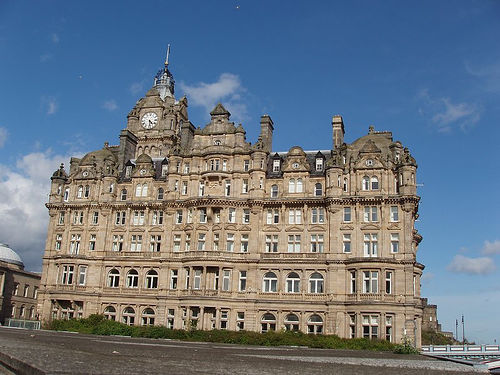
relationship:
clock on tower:
[127, 101, 182, 132] [114, 62, 202, 168]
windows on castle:
[336, 259, 449, 308] [45, 104, 431, 373]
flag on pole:
[154, 47, 180, 70] [141, 27, 194, 117]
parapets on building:
[75, 134, 379, 176] [47, 46, 433, 368]